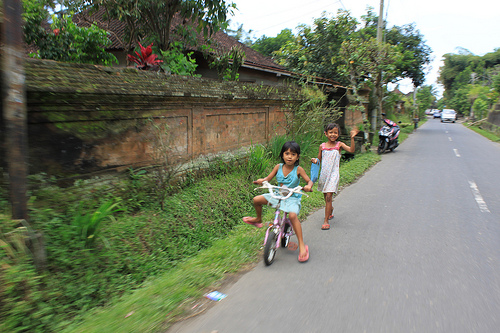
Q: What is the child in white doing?
A: Waving.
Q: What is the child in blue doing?
A: Riding a bike.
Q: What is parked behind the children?
A: Motorbike.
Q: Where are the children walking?
A: On the road.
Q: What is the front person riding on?
A: Bicycle.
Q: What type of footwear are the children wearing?
A: Flip flops.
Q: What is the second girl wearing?
A: Sundress.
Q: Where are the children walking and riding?
A: Street.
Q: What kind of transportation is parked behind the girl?
A: Motorcycle.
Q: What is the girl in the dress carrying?
A: Blue bag.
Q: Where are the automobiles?
A: On the road behind the girls.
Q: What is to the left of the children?
A: Wall.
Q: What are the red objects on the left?
A: Flowers.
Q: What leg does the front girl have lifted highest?
A: Right.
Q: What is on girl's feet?
A: Flip flops.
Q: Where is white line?
A: On road.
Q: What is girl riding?
A: Bike.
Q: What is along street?
A: A wall.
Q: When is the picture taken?
A: Daytime.